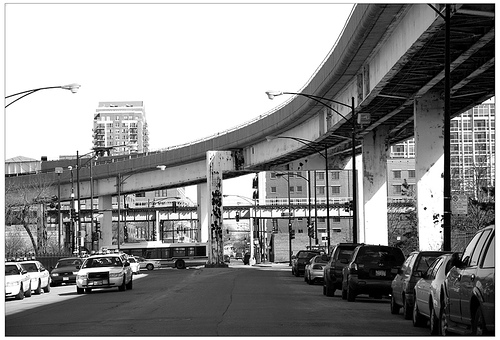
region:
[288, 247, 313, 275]
car parked in street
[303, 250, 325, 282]
car parked in street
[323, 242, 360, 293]
car parked in street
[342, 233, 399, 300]
car parked in street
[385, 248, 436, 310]
car parked in street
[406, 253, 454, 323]
car parked in street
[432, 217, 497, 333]
car parked in street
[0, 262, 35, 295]
car parked in street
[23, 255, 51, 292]
car parked in street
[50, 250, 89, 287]
car parked in street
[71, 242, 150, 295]
police car moving down the street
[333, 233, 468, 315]
cars parked on the side of the street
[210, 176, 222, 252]
graffiti on the column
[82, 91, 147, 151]
tall building behind the bridge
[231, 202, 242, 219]
traffic light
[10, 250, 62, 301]
two police cars parked on the side of the road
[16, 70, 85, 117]
street light hanging over the side of the road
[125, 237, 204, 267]
bus crossing the street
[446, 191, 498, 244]
tree growing by the road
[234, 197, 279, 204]
guard rail on the overpass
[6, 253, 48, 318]
car parked on the road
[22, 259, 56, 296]
car parked on the road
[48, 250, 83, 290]
car parked on the road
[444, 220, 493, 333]
car parked on the road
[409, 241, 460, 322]
car parked on the road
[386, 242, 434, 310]
car parked on the road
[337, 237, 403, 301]
car parked on the road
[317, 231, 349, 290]
car parked on the road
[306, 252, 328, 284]
car parked on the road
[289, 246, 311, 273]
car parked on the road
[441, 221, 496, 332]
vehicle parked on side of street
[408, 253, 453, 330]
vehicle parked on side of street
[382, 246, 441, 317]
vehicle parked on side of street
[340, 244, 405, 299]
vehicle parked on side of street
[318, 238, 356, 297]
vehicle parked on side of street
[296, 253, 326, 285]
vehicle parked on side of street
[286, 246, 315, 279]
vehicle parked on side of street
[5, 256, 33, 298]
vehicle parked on side of street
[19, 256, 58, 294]
vehicle parked on side of street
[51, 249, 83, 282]
vehicle parked on side of street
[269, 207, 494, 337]
the cars are parked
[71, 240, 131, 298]
a car on the street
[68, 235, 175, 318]
a car on the street